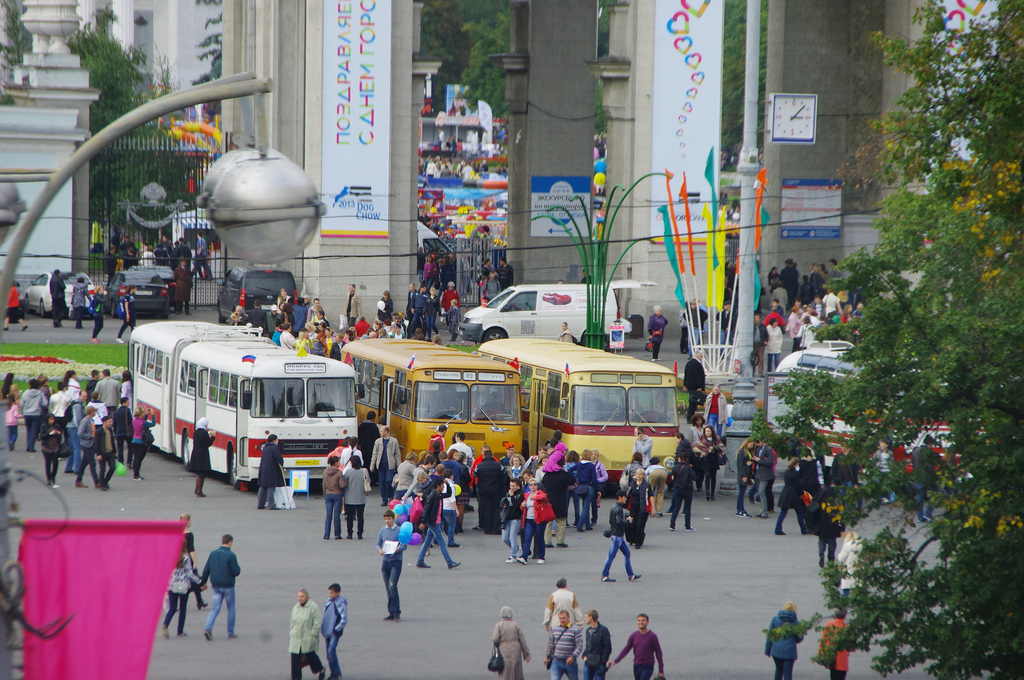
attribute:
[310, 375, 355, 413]
window — glass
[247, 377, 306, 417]
window — glass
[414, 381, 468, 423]
window — glass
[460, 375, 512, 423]
window — glass